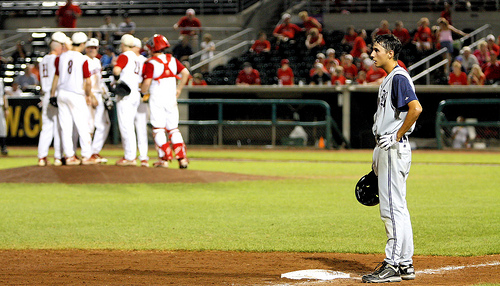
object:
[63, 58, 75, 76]
number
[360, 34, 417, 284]
player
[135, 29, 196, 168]
player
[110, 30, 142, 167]
player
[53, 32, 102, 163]
player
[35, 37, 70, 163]
player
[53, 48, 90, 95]
shirt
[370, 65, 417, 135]
shirt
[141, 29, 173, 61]
helmet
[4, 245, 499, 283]
clay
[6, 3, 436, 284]
baseball game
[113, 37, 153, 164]
baseball player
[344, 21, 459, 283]
player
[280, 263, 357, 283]
plate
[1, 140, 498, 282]
ground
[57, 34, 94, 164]
player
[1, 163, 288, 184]
pitcher's mound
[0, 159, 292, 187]
mound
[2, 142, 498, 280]
baseball field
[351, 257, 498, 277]
lines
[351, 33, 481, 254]
baseball player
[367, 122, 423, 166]
ground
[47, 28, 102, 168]
baseball player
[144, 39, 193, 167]
player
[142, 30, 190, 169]
man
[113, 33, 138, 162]
man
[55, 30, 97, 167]
man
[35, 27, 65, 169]
man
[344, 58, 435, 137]
shirts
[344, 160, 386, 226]
helmet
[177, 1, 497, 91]
crowd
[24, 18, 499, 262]
field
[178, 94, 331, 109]
green pole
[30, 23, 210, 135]
players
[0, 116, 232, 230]
mound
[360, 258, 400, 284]
shoes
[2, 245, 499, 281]
red clay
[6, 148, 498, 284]
field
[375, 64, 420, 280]
uniform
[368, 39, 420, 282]
player